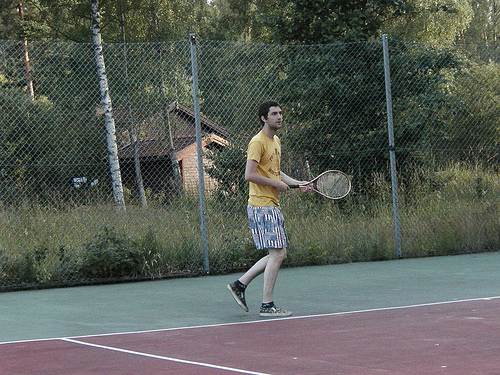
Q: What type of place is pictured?
A: It is a pavement.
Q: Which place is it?
A: It is a pavement.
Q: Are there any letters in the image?
A: Yes, there are letters.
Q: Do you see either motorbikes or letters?
A: Yes, there are letters.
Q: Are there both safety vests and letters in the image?
A: No, there are letters but no safety jackets.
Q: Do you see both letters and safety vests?
A: No, there are letters but no safety jackets.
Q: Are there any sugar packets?
A: No, there are no sugar packets.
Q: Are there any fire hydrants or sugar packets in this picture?
A: No, there are no sugar packets or fire hydrants.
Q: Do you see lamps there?
A: No, there are no lamps.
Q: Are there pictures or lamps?
A: No, there are no lamps or pictures.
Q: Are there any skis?
A: No, there are no skis.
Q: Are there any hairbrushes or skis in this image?
A: No, there are no skis or hairbrushes.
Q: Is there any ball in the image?
A: No, there are no balls.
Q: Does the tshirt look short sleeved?
A: Yes, the tshirt is short sleeved.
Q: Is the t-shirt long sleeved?
A: No, the t-shirt is short sleeved.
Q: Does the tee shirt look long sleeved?
A: No, the tee shirt is short sleeved.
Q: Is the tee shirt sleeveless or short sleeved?
A: The tee shirt is short sleeved.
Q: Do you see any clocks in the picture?
A: No, there are no clocks.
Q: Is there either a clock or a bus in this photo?
A: No, there are no clocks or buses.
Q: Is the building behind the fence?
A: Yes, the building is behind the fence.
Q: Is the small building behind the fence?
A: Yes, the building is behind the fence.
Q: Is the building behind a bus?
A: No, the building is behind the fence.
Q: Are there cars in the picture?
A: No, there are no cars.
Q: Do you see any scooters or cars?
A: No, there are no cars or scooters.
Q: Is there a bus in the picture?
A: No, there are no buses.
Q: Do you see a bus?
A: No, there are no buses.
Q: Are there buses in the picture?
A: No, there are no buses.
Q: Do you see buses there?
A: No, there are no buses.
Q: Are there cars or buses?
A: No, there are no buses or cars.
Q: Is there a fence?
A: Yes, there is a fence.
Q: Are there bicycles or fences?
A: Yes, there is a fence.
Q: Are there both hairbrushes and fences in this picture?
A: No, there is a fence but no hairbrushes.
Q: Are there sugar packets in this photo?
A: No, there are no sugar packets.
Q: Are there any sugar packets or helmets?
A: No, there are no sugar packets or helmets.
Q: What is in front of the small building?
A: The fence is in front of the building.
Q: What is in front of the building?
A: The fence is in front of the building.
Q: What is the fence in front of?
A: The fence is in front of the building.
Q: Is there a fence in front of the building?
A: Yes, there is a fence in front of the building.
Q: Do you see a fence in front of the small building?
A: Yes, there is a fence in front of the building.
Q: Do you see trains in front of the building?
A: No, there is a fence in front of the building.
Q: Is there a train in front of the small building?
A: No, there is a fence in front of the building.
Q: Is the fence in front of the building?
A: Yes, the fence is in front of the building.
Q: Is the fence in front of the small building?
A: Yes, the fence is in front of the building.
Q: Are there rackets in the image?
A: Yes, there is a racket.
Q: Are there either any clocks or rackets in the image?
A: Yes, there is a racket.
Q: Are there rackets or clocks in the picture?
A: Yes, there is a racket.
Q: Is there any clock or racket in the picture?
A: Yes, there is a racket.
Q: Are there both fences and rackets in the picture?
A: Yes, there are both a racket and a fence.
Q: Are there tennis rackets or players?
A: Yes, there is a tennis racket.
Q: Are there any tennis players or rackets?
A: Yes, there is a tennis racket.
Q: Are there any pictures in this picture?
A: No, there are no pictures.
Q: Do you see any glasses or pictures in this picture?
A: No, there are no pictures or glasses.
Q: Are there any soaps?
A: No, there are no soaps.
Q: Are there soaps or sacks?
A: No, there are no soaps or sacks.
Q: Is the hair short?
A: Yes, the hair is short.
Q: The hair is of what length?
A: The hair is short.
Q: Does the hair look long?
A: No, the hair is short.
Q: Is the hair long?
A: No, the hair is short.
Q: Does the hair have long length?
A: No, the hair is short.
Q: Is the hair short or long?
A: The hair is short.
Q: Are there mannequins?
A: No, there are no mannequins.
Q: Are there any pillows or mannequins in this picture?
A: No, there are no mannequins or pillows.